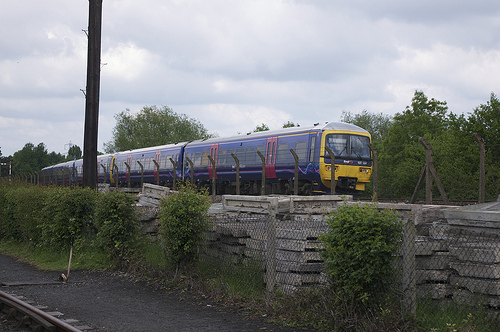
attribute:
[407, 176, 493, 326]
wall — concrete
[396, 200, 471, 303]
wall — concrete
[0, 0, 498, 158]
clouds — gray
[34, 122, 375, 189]
train — yellow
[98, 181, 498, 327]
squares — stacked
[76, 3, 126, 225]
pole — tall, wooden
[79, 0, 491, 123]
pallets — black 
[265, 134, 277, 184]
doors — red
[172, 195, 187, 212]
leaves — green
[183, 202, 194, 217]
leaves — green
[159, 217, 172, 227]
leaves — green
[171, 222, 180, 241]
leaves — green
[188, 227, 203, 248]
leaves — green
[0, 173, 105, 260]
bush — green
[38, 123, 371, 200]
train — yellow, blue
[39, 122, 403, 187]
train — red, blue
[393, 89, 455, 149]
leaves — green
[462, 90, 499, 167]
leaves — green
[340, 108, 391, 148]
leaves — green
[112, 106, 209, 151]
leaves — green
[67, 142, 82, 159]
leaves — green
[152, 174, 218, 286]
bush — green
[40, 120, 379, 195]
train — blue, yellow, red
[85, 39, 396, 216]
train — yellow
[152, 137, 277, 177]
doors — red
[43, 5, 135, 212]
pole — black 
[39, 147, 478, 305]
fence — metal, chain link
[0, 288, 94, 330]
train track — metal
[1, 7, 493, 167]
clouds — big, fluffy